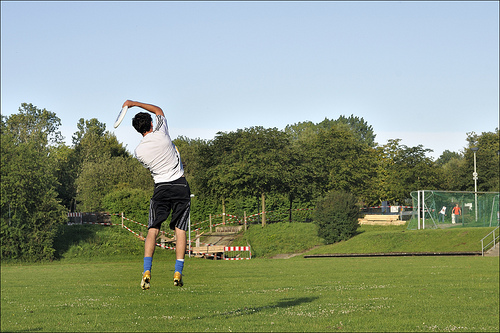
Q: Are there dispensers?
A: No, there are no dispensers.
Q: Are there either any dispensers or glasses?
A: No, there are no dispensers or glasses.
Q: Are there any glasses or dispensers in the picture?
A: No, there are no dispensers or glasses.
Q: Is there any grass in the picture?
A: Yes, there is grass.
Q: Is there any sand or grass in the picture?
A: Yes, there is grass.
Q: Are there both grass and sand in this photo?
A: No, there is grass but no sand.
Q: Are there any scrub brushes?
A: No, there are no scrub brushes.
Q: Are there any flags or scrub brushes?
A: No, there are no scrub brushes or flags.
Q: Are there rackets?
A: No, there are no rackets.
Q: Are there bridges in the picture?
A: Yes, there is a bridge.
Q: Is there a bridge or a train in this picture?
A: Yes, there is a bridge.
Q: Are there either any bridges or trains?
A: Yes, there is a bridge.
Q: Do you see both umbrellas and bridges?
A: No, there is a bridge but no umbrellas.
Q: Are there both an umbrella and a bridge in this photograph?
A: No, there is a bridge but no umbrellas.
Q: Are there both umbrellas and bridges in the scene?
A: No, there is a bridge but no umbrellas.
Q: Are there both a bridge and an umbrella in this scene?
A: No, there is a bridge but no umbrellas.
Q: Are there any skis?
A: No, there are no skis.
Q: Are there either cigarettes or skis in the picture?
A: No, there are no skis or cigarettes.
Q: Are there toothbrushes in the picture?
A: No, there are no toothbrushes.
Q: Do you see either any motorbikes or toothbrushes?
A: No, there are no toothbrushes or motorbikes.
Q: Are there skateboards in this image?
A: No, there are no skateboards.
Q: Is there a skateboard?
A: No, there are no skateboards.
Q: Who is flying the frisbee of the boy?
A: The boy is flying the frisbee.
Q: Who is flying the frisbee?
A: The boy is flying the frisbee.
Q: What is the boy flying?
A: The boy is flying the frisbee.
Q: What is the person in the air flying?
A: The boy is flying the frisbee.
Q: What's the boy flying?
A: The boy is flying the frisbee.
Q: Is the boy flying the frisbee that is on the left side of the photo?
A: Yes, the boy is flying the frisbee.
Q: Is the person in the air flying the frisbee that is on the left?
A: Yes, the boy is flying the frisbee.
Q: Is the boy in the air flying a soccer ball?
A: No, the boy is flying the frisbee.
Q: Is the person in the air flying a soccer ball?
A: No, the boy is flying the frisbee.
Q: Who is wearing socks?
A: The boy is wearing socks.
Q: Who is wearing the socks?
A: The boy is wearing socks.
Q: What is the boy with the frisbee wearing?
A: The boy is wearing socks.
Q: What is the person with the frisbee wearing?
A: The boy is wearing socks.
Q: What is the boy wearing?
A: The boy is wearing socks.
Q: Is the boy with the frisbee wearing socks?
A: Yes, the boy is wearing socks.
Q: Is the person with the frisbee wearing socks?
A: Yes, the boy is wearing socks.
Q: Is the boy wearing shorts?
A: No, the boy is wearing socks.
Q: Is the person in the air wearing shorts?
A: No, the boy is wearing socks.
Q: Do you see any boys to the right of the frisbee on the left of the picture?
A: Yes, there is a boy to the right of the frisbee.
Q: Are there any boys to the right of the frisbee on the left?
A: Yes, there is a boy to the right of the frisbee.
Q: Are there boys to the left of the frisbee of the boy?
A: No, the boy is to the right of the frisbee.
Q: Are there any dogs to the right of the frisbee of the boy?
A: No, there is a boy to the right of the frisbee.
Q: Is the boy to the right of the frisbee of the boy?
A: Yes, the boy is to the right of the frisbee.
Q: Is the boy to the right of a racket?
A: No, the boy is to the right of the frisbee.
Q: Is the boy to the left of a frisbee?
A: No, the boy is to the right of a frisbee.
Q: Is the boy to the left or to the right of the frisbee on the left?
A: The boy is to the right of the frisbee.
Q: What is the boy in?
A: The boy is in the air.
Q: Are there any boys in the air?
A: Yes, there is a boy in the air.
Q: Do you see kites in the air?
A: No, there is a boy in the air.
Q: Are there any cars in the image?
A: No, there are no cars.